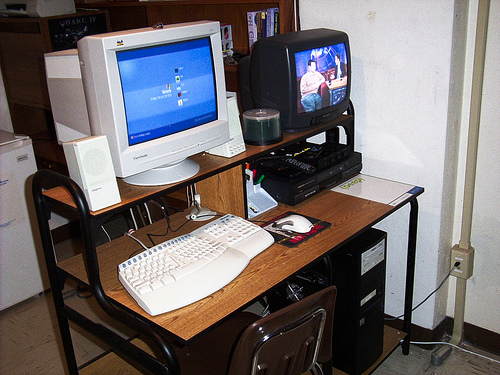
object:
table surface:
[315, 200, 372, 219]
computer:
[266, 227, 388, 374]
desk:
[50, 174, 421, 341]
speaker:
[62, 134, 122, 213]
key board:
[116, 212, 276, 317]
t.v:
[235, 27, 351, 133]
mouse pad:
[258, 211, 332, 247]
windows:
[150, 83, 172, 101]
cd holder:
[243, 108, 283, 145]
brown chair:
[173, 286, 340, 375]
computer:
[76, 21, 229, 187]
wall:
[295, 5, 498, 333]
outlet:
[450, 243, 474, 277]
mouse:
[271, 214, 314, 234]